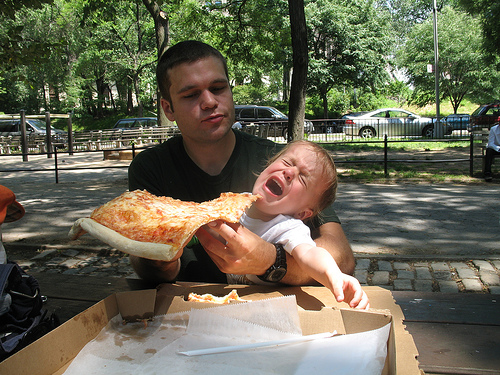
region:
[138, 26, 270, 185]
this is a man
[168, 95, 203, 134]
the man is light skinned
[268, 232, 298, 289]
this is a watch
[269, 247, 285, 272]
the watch is black in color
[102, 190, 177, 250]
this is a pizza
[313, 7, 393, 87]
this is a tree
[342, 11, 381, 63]
the leaves are green in color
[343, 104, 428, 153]
this is a car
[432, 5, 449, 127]
this is a pole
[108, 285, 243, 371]
this is a box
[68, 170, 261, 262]
a man holding a large pizza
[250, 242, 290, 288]
a man wearing a wrist watch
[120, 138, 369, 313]
a crying child eating food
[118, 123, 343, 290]
a man wearing a black shirt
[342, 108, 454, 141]
a silver car parked on a sidewalk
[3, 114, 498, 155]
a long metal fence by the side walk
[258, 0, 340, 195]
a large tree in the park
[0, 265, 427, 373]
an empty pizza box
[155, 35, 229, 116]
a man with black hair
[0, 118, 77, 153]
a silver car parked by the side walk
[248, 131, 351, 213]
head of a person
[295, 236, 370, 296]
arm of a person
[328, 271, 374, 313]
hand of a person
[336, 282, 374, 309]
finger of a person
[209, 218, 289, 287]
hand of a person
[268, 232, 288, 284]
wrist of a person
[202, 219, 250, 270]
finger of a person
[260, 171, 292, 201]
mouth of a person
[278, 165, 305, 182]
nose of a person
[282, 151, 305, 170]
eye of a person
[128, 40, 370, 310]
man holding a little boy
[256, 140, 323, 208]
boy appears to be crying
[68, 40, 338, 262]
man is holding a very large piece of pizza to boy's face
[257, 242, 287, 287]
man is wearing a black wristwatch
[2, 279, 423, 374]
an open brown pizza box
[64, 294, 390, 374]
white paper in pizza box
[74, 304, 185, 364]
grease stains on pizza box and paper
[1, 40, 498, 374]
dappled shadows falling across paved area behind man and boy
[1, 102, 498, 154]
cars on road visible beyond low fence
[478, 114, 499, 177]
seated man is visible at edge of image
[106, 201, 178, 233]
a large pizza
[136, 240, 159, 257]
the crust of the pizza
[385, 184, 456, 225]
shadows on the ground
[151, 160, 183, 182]
the man is wearing a black shirt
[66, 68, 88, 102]
the green leaves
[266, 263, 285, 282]
the man is wearing a watch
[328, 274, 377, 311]
the childs hand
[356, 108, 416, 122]
a car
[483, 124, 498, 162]
a person sitting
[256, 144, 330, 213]
the child is crying